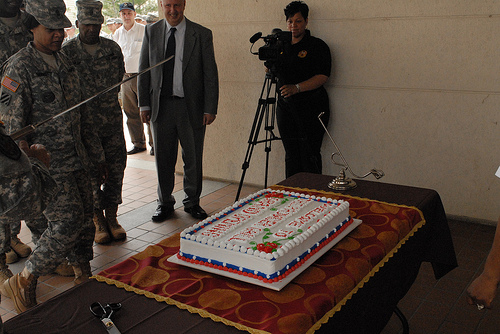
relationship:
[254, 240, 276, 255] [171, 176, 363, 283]
flower on cake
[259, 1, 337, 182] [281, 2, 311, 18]
woman has hair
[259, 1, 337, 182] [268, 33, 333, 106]
woman has shirt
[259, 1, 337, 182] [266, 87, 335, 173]
woman has pants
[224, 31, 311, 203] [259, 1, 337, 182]
camera behind woman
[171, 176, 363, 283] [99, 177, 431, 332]
cake on cloth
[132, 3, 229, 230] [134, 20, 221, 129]
man has coat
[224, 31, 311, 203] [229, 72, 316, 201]
camera on tripod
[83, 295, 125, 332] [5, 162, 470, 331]
scissors on table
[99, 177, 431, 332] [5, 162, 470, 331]
cloth on table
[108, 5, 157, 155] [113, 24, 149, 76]
man has shirt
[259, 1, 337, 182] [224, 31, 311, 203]
woman using camera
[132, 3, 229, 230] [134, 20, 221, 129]
man wearing coat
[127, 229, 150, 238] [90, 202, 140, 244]
tile under boots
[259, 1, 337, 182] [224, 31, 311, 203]
woman with camera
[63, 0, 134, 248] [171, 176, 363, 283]
soldier looking at cake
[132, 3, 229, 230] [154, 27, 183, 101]
man wearing tie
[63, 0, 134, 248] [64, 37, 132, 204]
soldier in uniform